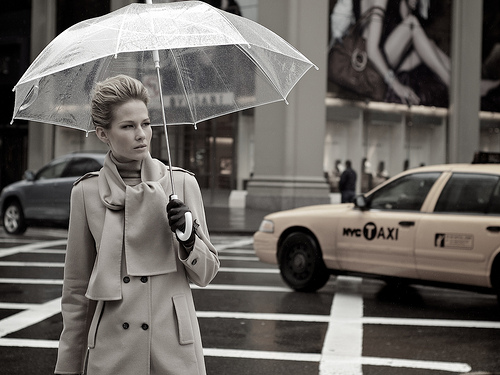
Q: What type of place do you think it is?
A: It is a road.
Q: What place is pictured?
A: It is a road.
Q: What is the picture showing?
A: It is showing a road.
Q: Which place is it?
A: It is a road.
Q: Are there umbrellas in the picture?
A: Yes, there is an umbrella.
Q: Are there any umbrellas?
A: Yes, there is an umbrella.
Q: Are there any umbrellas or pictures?
A: Yes, there is an umbrella.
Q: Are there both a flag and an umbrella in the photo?
A: No, there is an umbrella but no flags.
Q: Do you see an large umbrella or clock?
A: Yes, there is a large umbrella.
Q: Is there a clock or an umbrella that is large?
A: Yes, the umbrella is large.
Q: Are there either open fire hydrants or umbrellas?
A: Yes, there is an open umbrella.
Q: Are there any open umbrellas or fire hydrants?
A: Yes, there is an open umbrella.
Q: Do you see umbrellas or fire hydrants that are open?
A: Yes, the umbrella is open.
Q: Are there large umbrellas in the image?
A: Yes, there is a large umbrella.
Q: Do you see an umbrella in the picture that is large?
A: Yes, there is an umbrella that is large.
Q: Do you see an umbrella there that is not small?
A: Yes, there is a large umbrella.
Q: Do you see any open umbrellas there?
A: Yes, there is an open umbrella.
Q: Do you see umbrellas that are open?
A: Yes, there is an umbrella that is open.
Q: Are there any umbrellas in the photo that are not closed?
A: Yes, there is a open umbrella.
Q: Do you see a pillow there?
A: No, there are no pillows.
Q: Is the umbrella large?
A: Yes, the umbrella is large.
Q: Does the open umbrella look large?
A: Yes, the umbrella is large.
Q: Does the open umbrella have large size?
A: Yes, the umbrella is large.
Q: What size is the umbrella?
A: The umbrella is large.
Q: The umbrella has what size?
A: The umbrella is large.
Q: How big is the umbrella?
A: The umbrella is large.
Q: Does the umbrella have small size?
A: No, the umbrella is large.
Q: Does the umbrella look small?
A: No, the umbrella is large.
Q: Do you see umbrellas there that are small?
A: No, there is an umbrella but it is large.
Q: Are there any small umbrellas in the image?
A: No, there is an umbrella but it is large.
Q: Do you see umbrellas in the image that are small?
A: No, there is an umbrella but it is large.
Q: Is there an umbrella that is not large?
A: No, there is an umbrella but it is large.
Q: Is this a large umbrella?
A: Yes, this is a large umbrella.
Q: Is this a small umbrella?
A: No, this is a large umbrella.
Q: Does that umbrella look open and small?
A: No, the umbrella is open but large.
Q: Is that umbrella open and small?
A: No, the umbrella is open but large.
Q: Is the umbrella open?
A: Yes, the umbrella is open.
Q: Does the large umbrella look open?
A: Yes, the umbrella is open.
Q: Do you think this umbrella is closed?
A: No, the umbrella is open.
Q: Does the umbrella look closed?
A: No, the umbrella is open.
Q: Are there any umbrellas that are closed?
A: No, there is an umbrella but it is open.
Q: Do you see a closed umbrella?
A: No, there is an umbrella but it is open.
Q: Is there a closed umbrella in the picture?
A: No, there is an umbrella but it is open.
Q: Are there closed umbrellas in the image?
A: No, there is an umbrella but it is open.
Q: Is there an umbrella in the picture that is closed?
A: No, there is an umbrella but it is open.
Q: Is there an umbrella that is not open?
A: No, there is an umbrella but it is open.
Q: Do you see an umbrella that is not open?
A: No, there is an umbrella but it is open.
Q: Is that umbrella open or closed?
A: The umbrella is open.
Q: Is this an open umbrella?
A: Yes, this is an open umbrella.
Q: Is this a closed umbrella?
A: No, this is an open umbrella.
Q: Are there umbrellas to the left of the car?
A: Yes, there is an umbrella to the left of the car.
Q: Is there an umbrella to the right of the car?
A: No, the umbrella is to the left of the car.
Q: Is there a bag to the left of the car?
A: No, there is an umbrella to the left of the car.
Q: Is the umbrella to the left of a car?
A: Yes, the umbrella is to the left of a car.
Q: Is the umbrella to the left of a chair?
A: No, the umbrella is to the left of a car.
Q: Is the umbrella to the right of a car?
A: No, the umbrella is to the left of a car.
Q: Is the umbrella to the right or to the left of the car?
A: The umbrella is to the left of the car.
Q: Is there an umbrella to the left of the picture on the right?
A: Yes, there is an umbrella to the left of the picture.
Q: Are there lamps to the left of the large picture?
A: No, there is an umbrella to the left of the picture.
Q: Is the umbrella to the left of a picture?
A: Yes, the umbrella is to the left of a picture.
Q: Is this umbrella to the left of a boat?
A: No, the umbrella is to the left of a picture.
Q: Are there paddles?
A: No, there are no paddles.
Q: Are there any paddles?
A: No, there are no paddles.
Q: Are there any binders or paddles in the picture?
A: No, there are no paddles or binders.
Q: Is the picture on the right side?
A: Yes, the picture is on the right of the image.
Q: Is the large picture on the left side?
A: No, the picture is on the right of the image.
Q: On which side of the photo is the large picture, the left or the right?
A: The picture is on the right of the image.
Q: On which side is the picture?
A: The picture is on the right of the image.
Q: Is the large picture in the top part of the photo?
A: Yes, the picture is in the top of the image.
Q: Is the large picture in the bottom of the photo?
A: No, the picture is in the top of the image.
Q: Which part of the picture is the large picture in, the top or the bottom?
A: The picture is in the top of the image.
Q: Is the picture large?
A: Yes, the picture is large.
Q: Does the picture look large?
A: Yes, the picture is large.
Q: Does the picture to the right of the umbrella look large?
A: Yes, the picture is large.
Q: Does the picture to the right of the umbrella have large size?
A: Yes, the picture is large.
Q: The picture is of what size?
A: The picture is large.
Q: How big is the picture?
A: The picture is large.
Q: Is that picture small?
A: No, the picture is large.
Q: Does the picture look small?
A: No, the picture is large.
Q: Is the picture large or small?
A: The picture is large.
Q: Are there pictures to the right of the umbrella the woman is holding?
A: Yes, there is a picture to the right of the umbrella.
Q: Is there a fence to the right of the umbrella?
A: No, there is a picture to the right of the umbrella.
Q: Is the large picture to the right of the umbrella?
A: Yes, the picture is to the right of the umbrella.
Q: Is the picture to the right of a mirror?
A: No, the picture is to the right of the umbrella.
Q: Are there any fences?
A: No, there are no fences.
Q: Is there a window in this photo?
A: Yes, there is a window.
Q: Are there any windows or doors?
A: Yes, there is a window.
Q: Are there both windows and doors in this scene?
A: No, there is a window but no doors.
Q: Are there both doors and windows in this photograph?
A: No, there is a window but no doors.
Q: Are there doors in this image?
A: No, there are no doors.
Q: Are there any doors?
A: No, there are no doors.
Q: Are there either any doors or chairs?
A: No, there are no doors or chairs.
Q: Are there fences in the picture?
A: No, there are no fences.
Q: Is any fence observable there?
A: No, there are no fences.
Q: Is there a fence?
A: No, there are no fences.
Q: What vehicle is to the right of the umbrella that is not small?
A: The vehicle is a car.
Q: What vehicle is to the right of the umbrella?
A: The vehicle is a car.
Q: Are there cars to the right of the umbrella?
A: Yes, there is a car to the right of the umbrella.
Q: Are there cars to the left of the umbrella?
A: No, the car is to the right of the umbrella.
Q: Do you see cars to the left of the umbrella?
A: No, the car is to the right of the umbrella.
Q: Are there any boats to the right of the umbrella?
A: No, there is a car to the right of the umbrella.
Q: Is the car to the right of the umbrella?
A: Yes, the car is to the right of the umbrella.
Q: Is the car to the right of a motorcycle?
A: No, the car is to the right of the umbrella.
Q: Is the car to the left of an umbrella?
A: No, the car is to the right of an umbrella.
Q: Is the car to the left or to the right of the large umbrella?
A: The car is to the right of the umbrella.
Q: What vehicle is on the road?
A: The vehicle is a car.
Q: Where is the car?
A: The car is on the road.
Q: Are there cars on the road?
A: Yes, there is a car on the road.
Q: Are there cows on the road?
A: No, there is a car on the road.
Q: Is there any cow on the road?
A: No, there is a car on the road.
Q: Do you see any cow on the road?
A: No, there is a car on the road.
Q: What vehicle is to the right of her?
A: The vehicle is a car.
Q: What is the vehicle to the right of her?
A: The vehicle is a car.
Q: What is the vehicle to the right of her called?
A: The vehicle is a car.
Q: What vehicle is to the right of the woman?
A: The vehicle is a car.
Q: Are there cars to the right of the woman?
A: Yes, there is a car to the right of the woman.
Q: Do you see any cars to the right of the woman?
A: Yes, there is a car to the right of the woman.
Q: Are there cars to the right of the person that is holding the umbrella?
A: Yes, there is a car to the right of the woman.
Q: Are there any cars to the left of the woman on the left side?
A: No, the car is to the right of the woman.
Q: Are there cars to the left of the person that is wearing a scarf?
A: No, the car is to the right of the woman.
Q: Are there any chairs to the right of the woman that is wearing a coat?
A: No, there is a car to the right of the woman.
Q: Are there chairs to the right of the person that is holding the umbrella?
A: No, there is a car to the right of the woman.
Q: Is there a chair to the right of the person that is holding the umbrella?
A: No, there is a car to the right of the woman.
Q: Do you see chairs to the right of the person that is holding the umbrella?
A: No, there is a car to the right of the woman.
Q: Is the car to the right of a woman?
A: Yes, the car is to the right of a woman.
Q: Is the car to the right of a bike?
A: No, the car is to the right of a woman.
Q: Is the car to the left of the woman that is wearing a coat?
A: No, the car is to the right of the woman.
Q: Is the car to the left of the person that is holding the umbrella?
A: No, the car is to the right of the woman.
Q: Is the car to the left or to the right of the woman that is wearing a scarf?
A: The car is to the right of the woman.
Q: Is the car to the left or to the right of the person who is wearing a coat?
A: The car is to the right of the woman.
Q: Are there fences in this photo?
A: No, there are no fences.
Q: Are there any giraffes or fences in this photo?
A: No, there are no fences or giraffes.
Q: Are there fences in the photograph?
A: No, there are no fences.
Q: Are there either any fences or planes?
A: No, there are no fences or planes.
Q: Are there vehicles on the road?
A: Yes, there is a vehicle on the road.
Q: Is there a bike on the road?
A: No, there is a vehicle on the road.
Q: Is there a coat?
A: Yes, there is a coat.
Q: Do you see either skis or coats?
A: Yes, there is a coat.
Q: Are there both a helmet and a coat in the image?
A: No, there is a coat but no helmets.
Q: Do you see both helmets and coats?
A: No, there is a coat but no helmets.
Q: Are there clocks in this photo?
A: No, there are no clocks.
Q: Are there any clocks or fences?
A: No, there are no clocks or fences.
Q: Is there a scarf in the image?
A: Yes, there is a scarf.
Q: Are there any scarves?
A: Yes, there is a scarf.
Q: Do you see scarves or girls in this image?
A: Yes, there is a scarf.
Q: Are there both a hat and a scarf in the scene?
A: No, there is a scarf but no hats.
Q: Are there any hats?
A: No, there are no hats.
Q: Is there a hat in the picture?
A: No, there are no hats.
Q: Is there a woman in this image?
A: Yes, there is a woman.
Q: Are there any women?
A: Yes, there is a woman.